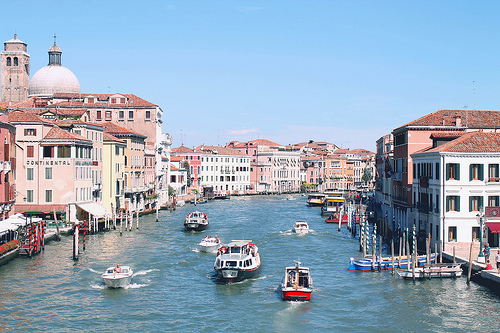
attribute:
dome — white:
[27, 33, 80, 94]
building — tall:
[14, 122, 97, 218]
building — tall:
[99, 133, 124, 216]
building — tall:
[98, 121, 153, 213]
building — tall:
[9, 92, 163, 209]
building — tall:
[161, 131, 167, 206]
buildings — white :
[168, 124, 390, 206]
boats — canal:
[346, 227, 466, 289]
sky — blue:
[99, 11, 489, 149]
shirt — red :
[110, 262, 120, 275]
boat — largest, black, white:
[215, 237, 260, 282]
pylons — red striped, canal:
[26, 219, 55, 250]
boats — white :
[337, 246, 444, 276]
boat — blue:
[353, 255, 431, 269]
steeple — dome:
[21, 36, 91, 112]